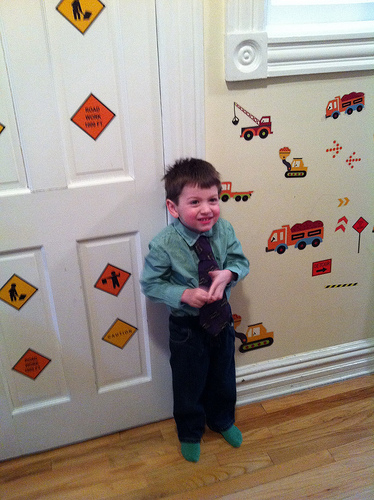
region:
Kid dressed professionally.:
[105, 157, 264, 465]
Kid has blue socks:
[163, 413, 253, 466]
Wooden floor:
[14, 463, 299, 498]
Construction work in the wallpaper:
[230, 97, 373, 286]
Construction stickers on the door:
[5, 257, 148, 398]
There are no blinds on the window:
[270, 1, 373, 28]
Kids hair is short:
[155, 146, 222, 217]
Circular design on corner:
[219, 23, 269, 81]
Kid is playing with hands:
[158, 266, 236, 318]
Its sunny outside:
[270, 0, 372, 25]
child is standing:
[139, 157, 248, 463]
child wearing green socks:
[179, 423, 242, 463]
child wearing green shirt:
[138, 215, 249, 317]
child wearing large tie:
[191, 235, 230, 338]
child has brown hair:
[162, 156, 222, 205]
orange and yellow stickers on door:
[0, 0, 138, 379]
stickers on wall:
[218, 91, 372, 352]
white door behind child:
[1, 0, 173, 461]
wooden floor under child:
[1, 370, 373, 498]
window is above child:
[267, 0, 372, 37]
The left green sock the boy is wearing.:
[177, 434, 207, 463]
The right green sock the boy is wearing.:
[220, 422, 248, 447]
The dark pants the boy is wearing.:
[169, 311, 241, 441]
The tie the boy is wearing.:
[186, 236, 231, 335]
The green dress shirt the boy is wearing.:
[153, 219, 242, 306]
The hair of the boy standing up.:
[158, 154, 226, 199]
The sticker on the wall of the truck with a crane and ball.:
[230, 95, 273, 148]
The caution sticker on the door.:
[95, 310, 144, 360]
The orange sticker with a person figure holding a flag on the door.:
[85, 261, 135, 301]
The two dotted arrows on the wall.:
[316, 137, 368, 174]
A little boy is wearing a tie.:
[139, 152, 262, 465]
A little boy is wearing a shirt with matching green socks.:
[138, 152, 272, 472]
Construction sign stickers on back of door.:
[0, 259, 149, 386]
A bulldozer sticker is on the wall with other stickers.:
[274, 142, 315, 183]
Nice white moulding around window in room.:
[218, 2, 372, 89]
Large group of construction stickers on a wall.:
[209, 90, 372, 358]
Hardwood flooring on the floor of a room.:
[241, 404, 371, 492]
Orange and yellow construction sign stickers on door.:
[0, 260, 150, 394]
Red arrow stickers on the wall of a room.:
[316, 129, 368, 179]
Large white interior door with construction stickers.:
[1, 0, 208, 460]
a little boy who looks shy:
[149, 159, 285, 453]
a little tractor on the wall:
[227, 96, 305, 142]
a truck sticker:
[261, 220, 351, 258]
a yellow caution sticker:
[89, 318, 154, 363]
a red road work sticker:
[63, 90, 121, 141]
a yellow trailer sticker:
[280, 140, 321, 192]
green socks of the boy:
[164, 430, 266, 465]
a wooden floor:
[274, 428, 354, 487]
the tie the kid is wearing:
[179, 238, 261, 371]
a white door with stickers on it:
[1, 171, 165, 418]